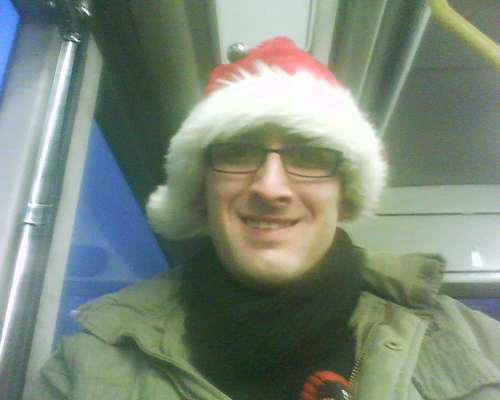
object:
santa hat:
[144, 36, 387, 240]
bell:
[226, 42, 249, 64]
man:
[35, 36, 499, 400]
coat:
[23, 245, 498, 400]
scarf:
[178, 227, 367, 400]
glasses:
[204, 140, 346, 179]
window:
[52, 117, 174, 355]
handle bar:
[426, 0, 499, 70]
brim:
[144, 57, 388, 242]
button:
[384, 340, 403, 351]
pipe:
[0, 27, 81, 400]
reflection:
[471, 251, 483, 268]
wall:
[336, 182, 500, 297]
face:
[195, 124, 355, 293]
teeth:
[242, 219, 297, 230]